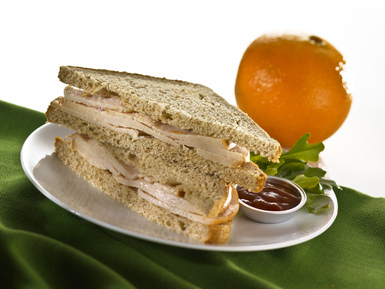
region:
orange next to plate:
[243, 11, 366, 163]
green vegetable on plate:
[252, 127, 327, 218]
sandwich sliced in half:
[52, 79, 258, 240]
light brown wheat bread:
[85, 48, 237, 141]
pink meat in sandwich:
[64, 80, 233, 139]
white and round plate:
[33, 106, 345, 262]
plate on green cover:
[14, 103, 327, 249]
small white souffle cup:
[241, 165, 294, 221]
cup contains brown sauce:
[245, 161, 293, 218]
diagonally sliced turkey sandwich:
[69, 76, 265, 265]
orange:
[228, 25, 360, 134]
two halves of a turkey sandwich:
[32, 52, 259, 257]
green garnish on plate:
[282, 141, 372, 180]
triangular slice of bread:
[71, 58, 277, 119]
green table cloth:
[33, 219, 122, 286]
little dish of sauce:
[246, 178, 314, 228]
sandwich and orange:
[21, 11, 365, 259]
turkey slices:
[73, 139, 244, 182]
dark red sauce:
[242, 194, 298, 209]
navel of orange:
[301, 33, 341, 60]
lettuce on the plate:
[307, 154, 321, 166]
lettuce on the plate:
[314, 200, 326, 211]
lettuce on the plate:
[298, 173, 315, 188]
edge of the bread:
[262, 148, 277, 169]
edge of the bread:
[243, 177, 267, 194]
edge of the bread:
[203, 179, 218, 205]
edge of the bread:
[198, 227, 225, 238]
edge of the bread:
[135, 99, 151, 122]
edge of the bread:
[108, 127, 129, 146]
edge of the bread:
[95, 177, 110, 194]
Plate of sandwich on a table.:
[13, 64, 348, 253]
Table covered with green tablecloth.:
[0, 248, 380, 278]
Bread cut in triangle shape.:
[44, 65, 283, 245]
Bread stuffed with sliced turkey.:
[52, 88, 255, 233]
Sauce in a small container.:
[237, 174, 304, 214]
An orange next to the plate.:
[231, 27, 353, 138]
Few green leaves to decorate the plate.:
[258, 137, 335, 191]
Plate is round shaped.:
[15, 114, 345, 250]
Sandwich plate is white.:
[19, 117, 340, 250]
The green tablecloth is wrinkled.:
[1, 255, 284, 287]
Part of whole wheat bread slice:
[141, 83, 196, 105]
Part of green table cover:
[337, 233, 371, 269]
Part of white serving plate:
[240, 228, 284, 242]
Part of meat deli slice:
[149, 190, 185, 212]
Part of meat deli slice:
[83, 144, 108, 174]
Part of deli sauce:
[268, 194, 291, 201]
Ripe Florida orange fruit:
[257, 58, 320, 101]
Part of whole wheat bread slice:
[117, 190, 141, 207]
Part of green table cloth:
[37, 247, 119, 269]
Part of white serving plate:
[39, 166, 61, 185]